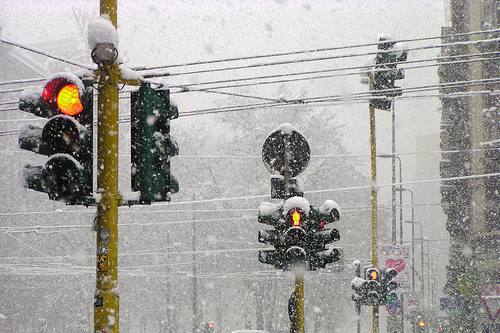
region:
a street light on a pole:
[22, 68, 183, 210]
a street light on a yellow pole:
[24, 49, 173, 220]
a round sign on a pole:
[254, 123, 336, 200]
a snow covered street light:
[364, 37, 406, 123]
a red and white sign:
[373, 242, 419, 274]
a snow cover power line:
[231, 29, 472, 138]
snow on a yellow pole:
[87, 8, 134, 51]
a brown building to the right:
[422, 22, 495, 257]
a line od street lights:
[378, 144, 445, 267]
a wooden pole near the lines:
[186, 181, 201, 318]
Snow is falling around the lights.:
[14, 21, 496, 331]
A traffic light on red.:
[20, 74, 90, 201]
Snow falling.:
[1, 6, 498, 331]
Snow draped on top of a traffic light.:
[252, 190, 346, 220]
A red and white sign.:
[472, 292, 497, 327]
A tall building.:
[440, 5, 497, 326]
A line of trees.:
[126, 96, 356, 326]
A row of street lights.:
[371, 145, 434, 330]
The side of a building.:
[0, 32, 145, 267]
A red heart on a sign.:
[375, 240, 412, 291]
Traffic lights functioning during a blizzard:
[44, 64, 407, 312]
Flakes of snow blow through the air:
[134, 214, 256, 314]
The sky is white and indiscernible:
[137, 8, 303, 46]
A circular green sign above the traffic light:
[261, 126, 313, 178]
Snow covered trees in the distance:
[177, 135, 276, 307]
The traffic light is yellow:
[55, 83, 95, 115]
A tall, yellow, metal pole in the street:
[87, 74, 127, 331]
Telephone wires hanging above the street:
[173, 55, 389, 120]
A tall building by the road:
[440, 37, 497, 264]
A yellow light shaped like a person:
[290, 209, 302, 226]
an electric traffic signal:
[41, 72, 91, 200]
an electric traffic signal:
[18, 80, 44, 192]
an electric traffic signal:
[370, 35, 405, 100]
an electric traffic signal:
[127, 87, 181, 199]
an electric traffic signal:
[280, 197, 308, 268]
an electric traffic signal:
[256, 205, 281, 264]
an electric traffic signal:
[307, 201, 341, 272]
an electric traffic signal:
[363, 265, 381, 307]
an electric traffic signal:
[352, 280, 366, 304]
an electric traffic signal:
[382, 268, 399, 307]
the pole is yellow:
[70, 32, 151, 324]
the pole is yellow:
[277, 261, 317, 327]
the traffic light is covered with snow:
[236, 185, 359, 239]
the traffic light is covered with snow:
[59, 13, 181, 113]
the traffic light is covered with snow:
[247, 170, 377, 259]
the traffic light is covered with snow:
[366, 23, 416, 136]